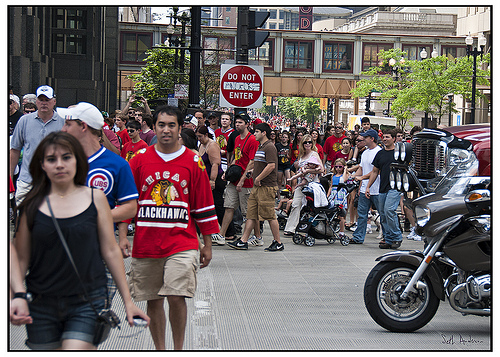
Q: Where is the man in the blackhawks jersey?
A: In the crosswalk.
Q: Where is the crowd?
A: Across the street.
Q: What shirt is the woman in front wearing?
A: A black tank-top.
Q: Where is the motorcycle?
A: The road.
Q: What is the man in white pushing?
A: The stroller.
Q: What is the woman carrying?
A: The purse.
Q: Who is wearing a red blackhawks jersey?
A: A man.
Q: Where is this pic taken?
A: Intersection.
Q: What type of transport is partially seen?
A: A motorcycle.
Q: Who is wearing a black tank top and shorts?
A: A woman.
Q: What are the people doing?
A: Crossing the street.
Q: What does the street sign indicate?
A: So not enter.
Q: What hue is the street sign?
A: Red and white.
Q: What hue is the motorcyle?
A: Black and silver.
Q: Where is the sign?
A: On the pole.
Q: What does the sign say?
A: Do not enter.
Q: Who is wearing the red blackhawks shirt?
A: The man.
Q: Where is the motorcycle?
A: On the raod.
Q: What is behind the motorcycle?
A: The truck.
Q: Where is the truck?
A: Behind the motorcycle.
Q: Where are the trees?
A: Behind the crowd.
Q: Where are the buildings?
A: Behind the trees.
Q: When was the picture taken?
A: Daytime.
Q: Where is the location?
A: Downtown.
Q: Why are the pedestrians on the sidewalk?
A: Walking.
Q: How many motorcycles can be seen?
A: One.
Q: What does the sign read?
A: Do Not Enter.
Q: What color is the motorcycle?
A: Black.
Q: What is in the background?
A: Building.